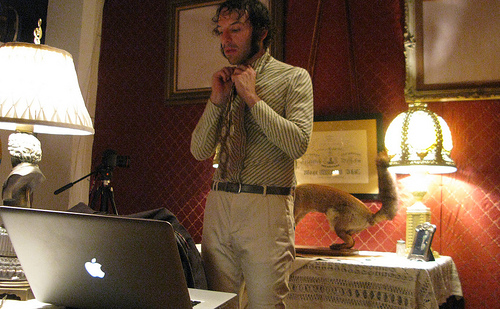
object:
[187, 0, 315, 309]
man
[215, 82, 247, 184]
tie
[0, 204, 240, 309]
laptop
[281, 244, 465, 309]
table cloth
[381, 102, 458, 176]
lamp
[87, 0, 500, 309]
wall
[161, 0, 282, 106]
photo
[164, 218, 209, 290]
luggage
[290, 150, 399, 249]
cat